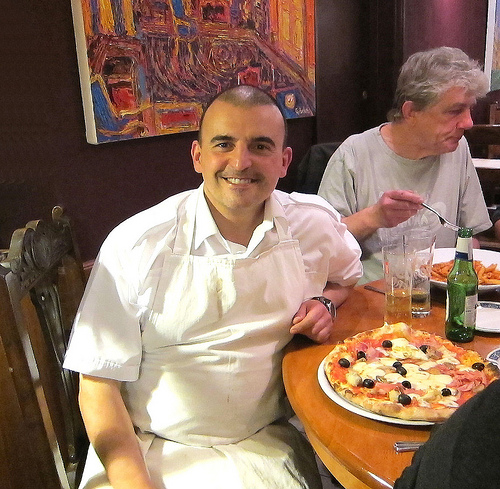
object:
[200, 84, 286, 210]
head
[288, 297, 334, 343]
hand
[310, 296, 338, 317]
watch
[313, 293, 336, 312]
wrist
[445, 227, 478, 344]
bottle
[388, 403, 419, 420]
pizza pie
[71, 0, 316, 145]
painting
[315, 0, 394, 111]
wall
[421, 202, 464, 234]
fork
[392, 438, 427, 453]
handle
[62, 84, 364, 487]
man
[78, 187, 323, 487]
apron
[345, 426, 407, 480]
table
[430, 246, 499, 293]
plate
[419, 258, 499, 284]
pasta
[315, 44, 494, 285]
man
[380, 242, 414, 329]
glass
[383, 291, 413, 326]
beer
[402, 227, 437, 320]
glass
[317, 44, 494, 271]
man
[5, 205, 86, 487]
chair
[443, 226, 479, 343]
wine bottle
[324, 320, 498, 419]
pizza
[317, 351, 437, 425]
plate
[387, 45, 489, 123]
hair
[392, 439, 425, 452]
service utensil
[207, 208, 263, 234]
neck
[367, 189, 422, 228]
man's hand